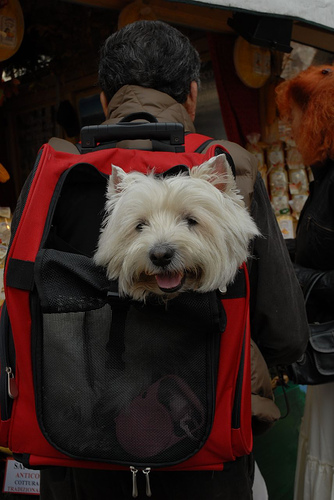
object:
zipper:
[7, 365, 19, 399]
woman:
[273, 75, 333, 500]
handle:
[81, 121, 185, 146]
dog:
[93, 153, 267, 415]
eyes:
[181, 213, 200, 228]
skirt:
[292, 385, 333, 499]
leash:
[114, 372, 206, 458]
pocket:
[39, 298, 210, 461]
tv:
[80, 115, 186, 156]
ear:
[190, 80, 197, 122]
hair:
[277, 64, 333, 163]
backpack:
[3, 122, 263, 478]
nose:
[150, 247, 174, 263]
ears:
[109, 163, 128, 200]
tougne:
[156, 275, 180, 289]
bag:
[288, 256, 332, 384]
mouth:
[145, 264, 192, 293]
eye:
[135, 221, 148, 232]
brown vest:
[2, 84, 280, 440]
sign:
[1, 458, 44, 497]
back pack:
[0, 132, 253, 474]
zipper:
[141, 466, 152, 497]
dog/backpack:
[1, 132, 255, 476]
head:
[98, 20, 199, 106]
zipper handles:
[128, 465, 151, 496]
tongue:
[155, 272, 181, 287]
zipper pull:
[142, 466, 152, 498]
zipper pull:
[128, 464, 139, 498]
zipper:
[202, 341, 217, 446]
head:
[99, 154, 259, 305]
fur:
[105, 181, 166, 248]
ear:
[192, 154, 231, 193]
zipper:
[131, 463, 139, 498]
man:
[0, 19, 310, 498]